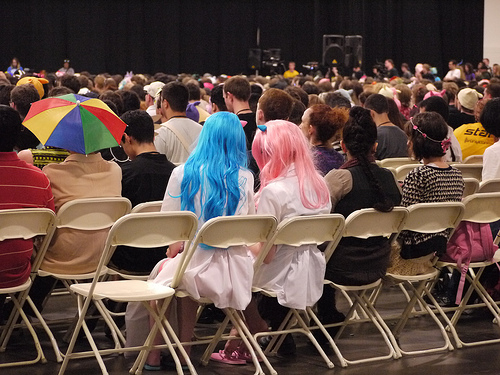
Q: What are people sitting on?
A: A chair.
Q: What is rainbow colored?
A: An umbrella.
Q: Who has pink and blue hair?
A: The women.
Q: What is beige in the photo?
A: The seats.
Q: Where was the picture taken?
A: At a convention.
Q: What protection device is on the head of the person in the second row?
A: A umbrella.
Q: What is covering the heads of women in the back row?
A: Wigs.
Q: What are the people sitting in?
A: Chairs.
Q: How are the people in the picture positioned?
A: Sitting.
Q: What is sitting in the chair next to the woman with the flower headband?
A: A backpack.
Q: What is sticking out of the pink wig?
A: Horns.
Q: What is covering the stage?
A: A curtain.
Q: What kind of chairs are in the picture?
A: Folding.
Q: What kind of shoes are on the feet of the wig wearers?
A: Flip flops.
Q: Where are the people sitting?
A: In an auditorium.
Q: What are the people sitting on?
A: White folding chairs.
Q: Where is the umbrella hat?
A: Person on left.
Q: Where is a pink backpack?
A: On the sixth chair.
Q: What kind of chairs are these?
A: Folding.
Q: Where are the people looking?
A: Toward the front of the stage.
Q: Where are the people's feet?
A: On the floor.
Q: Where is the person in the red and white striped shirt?
A: On the far left.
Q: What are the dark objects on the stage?
A: Speakers.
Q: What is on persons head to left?
A: Umbrella.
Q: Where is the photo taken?
A: At a play.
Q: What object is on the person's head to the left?
A: An umbrella.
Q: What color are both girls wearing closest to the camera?
A: White.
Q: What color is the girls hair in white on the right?
A: Pink.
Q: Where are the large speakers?
A: Stage side right.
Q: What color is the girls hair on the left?
A: Blue.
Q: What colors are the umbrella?
A: Blue, yellow, green and red.